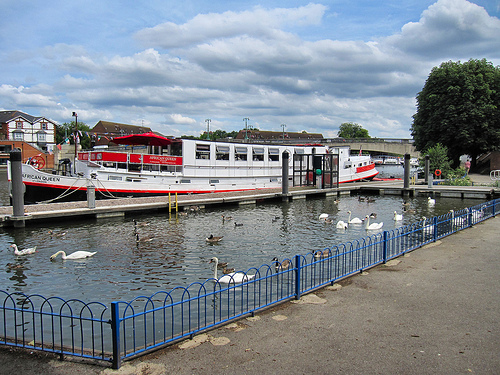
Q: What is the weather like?
A: It is cloudy.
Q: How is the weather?
A: It is cloudy.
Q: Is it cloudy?
A: Yes, it is cloudy.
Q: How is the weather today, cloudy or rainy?
A: It is cloudy.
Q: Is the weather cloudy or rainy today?
A: It is cloudy.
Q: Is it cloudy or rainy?
A: It is cloudy.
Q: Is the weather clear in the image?
A: No, it is cloudy.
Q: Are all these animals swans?
A: No, there are both geese and swans.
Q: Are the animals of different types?
A: Yes, they are geese and swans.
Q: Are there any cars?
A: No, there are no cars.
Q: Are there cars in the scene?
A: No, there are no cars.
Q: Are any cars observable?
A: No, there are no cars.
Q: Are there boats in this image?
A: Yes, there is a boat.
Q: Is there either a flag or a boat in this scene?
A: Yes, there is a boat.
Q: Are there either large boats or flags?
A: Yes, there is a large boat.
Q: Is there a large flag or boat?
A: Yes, there is a large boat.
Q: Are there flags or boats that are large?
A: Yes, the boat is large.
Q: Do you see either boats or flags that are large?
A: Yes, the boat is large.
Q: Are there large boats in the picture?
A: Yes, there is a large boat.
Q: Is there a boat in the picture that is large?
A: Yes, there is a boat that is large.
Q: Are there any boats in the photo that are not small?
A: Yes, there is a large boat.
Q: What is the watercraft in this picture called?
A: The watercraft is a boat.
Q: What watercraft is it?
A: The watercraft is a boat.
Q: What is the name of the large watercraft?
A: The watercraft is a boat.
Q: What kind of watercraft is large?
A: The watercraft is a boat.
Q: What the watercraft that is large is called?
A: The watercraft is a boat.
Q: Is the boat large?
A: Yes, the boat is large.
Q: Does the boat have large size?
A: Yes, the boat is large.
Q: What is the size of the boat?
A: The boat is large.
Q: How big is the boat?
A: The boat is large.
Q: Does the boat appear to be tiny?
A: No, the boat is large.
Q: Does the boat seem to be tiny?
A: No, the boat is large.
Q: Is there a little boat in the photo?
A: No, there is a boat but it is large.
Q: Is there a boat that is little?
A: No, there is a boat but it is large.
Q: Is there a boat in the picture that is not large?
A: No, there is a boat but it is large.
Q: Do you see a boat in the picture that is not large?
A: No, there is a boat but it is large.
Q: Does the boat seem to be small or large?
A: The boat is large.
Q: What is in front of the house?
A: The boat is in front of the house.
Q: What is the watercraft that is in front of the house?
A: The watercraft is a boat.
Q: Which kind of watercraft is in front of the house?
A: The watercraft is a boat.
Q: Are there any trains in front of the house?
A: No, there is a boat in front of the house.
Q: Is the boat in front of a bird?
A: No, the boat is in front of the house.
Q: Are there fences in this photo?
A: Yes, there is a fence.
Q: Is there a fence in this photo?
A: Yes, there is a fence.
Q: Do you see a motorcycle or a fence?
A: Yes, there is a fence.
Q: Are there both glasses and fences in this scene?
A: No, there is a fence but no glasses.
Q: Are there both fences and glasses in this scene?
A: No, there is a fence but no glasses.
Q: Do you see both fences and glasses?
A: No, there is a fence but no glasses.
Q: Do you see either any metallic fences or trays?
A: Yes, there is a metal fence.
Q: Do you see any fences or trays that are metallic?
A: Yes, the fence is metallic.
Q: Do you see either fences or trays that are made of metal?
A: Yes, the fence is made of metal.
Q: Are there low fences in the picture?
A: Yes, there is a low fence.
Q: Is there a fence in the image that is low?
A: Yes, there is a fence that is low.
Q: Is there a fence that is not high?
A: Yes, there is a low fence.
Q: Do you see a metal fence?
A: Yes, there is a fence that is made of metal.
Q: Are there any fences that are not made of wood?
A: Yes, there is a fence that is made of metal.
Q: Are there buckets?
A: No, there are no buckets.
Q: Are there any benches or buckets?
A: No, there are no buckets or benches.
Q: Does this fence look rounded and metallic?
A: Yes, the fence is rounded and metallic.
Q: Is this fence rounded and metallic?
A: Yes, the fence is rounded and metallic.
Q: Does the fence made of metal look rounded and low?
A: Yes, the fence is rounded and low.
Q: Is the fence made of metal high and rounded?
A: No, the fence is rounded but low.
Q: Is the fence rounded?
A: Yes, the fence is rounded.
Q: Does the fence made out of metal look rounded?
A: Yes, the fence is rounded.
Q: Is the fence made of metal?
A: Yes, the fence is made of metal.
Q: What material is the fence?
A: The fence is made of metal.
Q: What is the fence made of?
A: The fence is made of metal.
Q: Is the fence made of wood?
A: No, the fence is made of metal.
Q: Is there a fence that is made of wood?
A: No, there is a fence but it is made of metal.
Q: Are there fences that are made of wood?
A: No, there is a fence but it is made of metal.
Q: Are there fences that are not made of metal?
A: No, there is a fence but it is made of metal.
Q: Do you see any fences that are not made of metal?
A: No, there is a fence but it is made of metal.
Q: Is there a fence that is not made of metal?
A: No, there is a fence but it is made of metal.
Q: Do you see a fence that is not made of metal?
A: No, there is a fence but it is made of metal.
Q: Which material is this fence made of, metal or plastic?
A: The fence is made of metal.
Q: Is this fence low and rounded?
A: Yes, the fence is low and rounded.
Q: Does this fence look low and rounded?
A: Yes, the fence is low and rounded.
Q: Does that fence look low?
A: Yes, the fence is low.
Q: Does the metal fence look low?
A: Yes, the fence is low.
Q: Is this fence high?
A: No, the fence is low.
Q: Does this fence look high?
A: No, the fence is low.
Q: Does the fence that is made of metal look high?
A: No, the fence is low.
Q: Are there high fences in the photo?
A: No, there is a fence but it is low.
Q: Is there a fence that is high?
A: No, there is a fence but it is low.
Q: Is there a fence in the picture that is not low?
A: No, there is a fence but it is low.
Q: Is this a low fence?
A: Yes, this is a low fence.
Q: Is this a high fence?
A: No, this is a low fence.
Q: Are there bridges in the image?
A: Yes, there is a bridge.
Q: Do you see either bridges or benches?
A: Yes, there is a bridge.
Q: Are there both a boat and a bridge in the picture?
A: Yes, there are both a bridge and a boat.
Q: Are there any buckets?
A: No, there are no buckets.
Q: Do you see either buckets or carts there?
A: No, there are no buckets or carts.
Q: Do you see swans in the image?
A: Yes, there is a swan.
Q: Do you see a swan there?
A: Yes, there is a swan.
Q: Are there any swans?
A: Yes, there is a swan.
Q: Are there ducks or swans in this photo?
A: Yes, there is a swan.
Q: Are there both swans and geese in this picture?
A: Yes, there are both a swan and geese.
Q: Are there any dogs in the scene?
A: No, there are no dogs.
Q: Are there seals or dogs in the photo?
A: No, there are no dogs or seals.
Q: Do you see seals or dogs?
A: No, there are no dogs or seals.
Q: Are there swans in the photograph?
A: Yes, there is a swan.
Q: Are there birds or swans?
A: Yes, there is a swan.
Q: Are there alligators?
A: No, there are no alligators.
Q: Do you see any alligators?
A: No, there are no alligators.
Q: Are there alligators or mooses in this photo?
A: No, there are no alligators or mooses.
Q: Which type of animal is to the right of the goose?
A: The animal is a swan.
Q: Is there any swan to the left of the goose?
A: No, the swan is to the right of the goose.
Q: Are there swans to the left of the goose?
A: No, the swan is to the right of the goose.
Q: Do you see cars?
A: No, there are no cars.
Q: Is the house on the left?
A: Yes, the house is on the left of the image.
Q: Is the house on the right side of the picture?
A: No, the house is on the left of the image.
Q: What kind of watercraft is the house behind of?
A: The house is behind the boat.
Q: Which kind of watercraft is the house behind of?
A: The house is behind the boat.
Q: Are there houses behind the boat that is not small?
A: Yes, there is a house behind the boat.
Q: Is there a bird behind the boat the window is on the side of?
A: No, there is a house behind the boat.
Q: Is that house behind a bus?
A: No, the house is behind the boat.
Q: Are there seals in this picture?
A: No, there are no seals.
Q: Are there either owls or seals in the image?
A: No, there are no seals or owls.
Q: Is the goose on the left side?
A: Yes, the goose is on the left of the image.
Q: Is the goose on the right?
A: No, the goose is on the left of the image.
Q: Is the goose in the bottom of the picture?
A: Yes, the goose is in the bottom of the image.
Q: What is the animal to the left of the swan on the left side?
A: The animal is a goose.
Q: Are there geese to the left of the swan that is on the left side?
A: Yes, there is a goose to the left of the swan.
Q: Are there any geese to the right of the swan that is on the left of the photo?
A: No, the goose is to the left of the swan.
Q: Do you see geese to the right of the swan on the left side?
A: No, the goose is to the left of the swan.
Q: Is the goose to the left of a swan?
A: Yes, the goose is to the left of a swan.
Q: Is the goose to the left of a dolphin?
A: No, the goose is to the left of a swan.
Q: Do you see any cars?
A: No, there are no cars.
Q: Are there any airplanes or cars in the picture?
A: No, there are no cars or airplanes.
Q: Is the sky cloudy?
A: Yes, the sky is cloudy.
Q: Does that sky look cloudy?
A: Yes, the sky is cloudy.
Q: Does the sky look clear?
A: No, the sky is cloudy.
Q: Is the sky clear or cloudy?
A: The sky is cloudy.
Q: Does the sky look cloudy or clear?
A: The sky is cloudy.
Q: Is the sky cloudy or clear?
A: The sky is cloudy.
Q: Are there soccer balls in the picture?
A: No, there are no soccer balls.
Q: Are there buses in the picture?
A: No, there are no buses.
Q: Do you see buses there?
A: No, there are no buses.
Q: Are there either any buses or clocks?
A: No, there are no buses or clocks.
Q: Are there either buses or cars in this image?
A: No, there are no cars or buses.